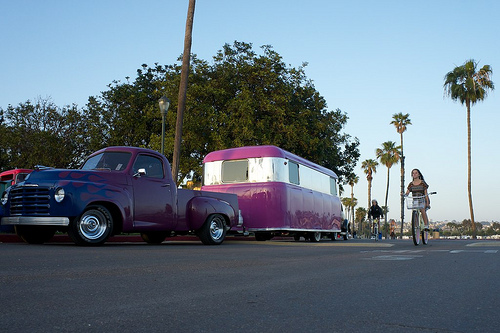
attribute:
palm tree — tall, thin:
[444, 59, 493, 237]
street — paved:
[6, 234, 494, 324]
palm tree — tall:
[396, 115, 410, 239]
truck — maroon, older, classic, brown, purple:
[7, 146, 241, 245]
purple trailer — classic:
[205, 146, 348, 239]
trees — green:
[5, 43, 351, 241]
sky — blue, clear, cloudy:
[6, 5, 492, 101]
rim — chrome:
[76, 211, 110, 237]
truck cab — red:
[2, 162, 34, 190]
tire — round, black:
[203, 214, 231, 242]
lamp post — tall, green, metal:
[153, 92, 173, 154]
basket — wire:
[404, 191, 440, 211]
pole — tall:
[170, 0, 200, 181]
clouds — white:
[370, 185, 496, 224]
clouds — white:
[355, 26, 436, 108]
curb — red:
[10, 232, 250, 243]